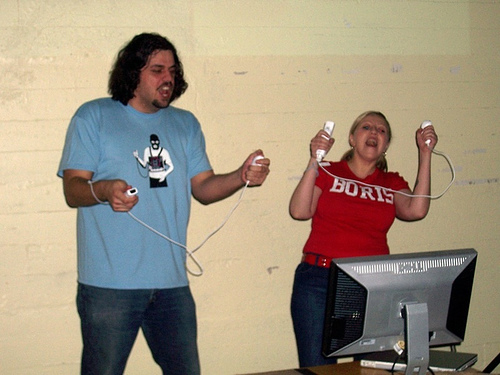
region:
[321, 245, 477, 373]
back of dell monitor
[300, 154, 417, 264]
red shirt reading "boris"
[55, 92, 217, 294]
blue shirt with cartoon print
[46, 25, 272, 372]
man with medium-length black hair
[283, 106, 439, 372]
woman with blonde hair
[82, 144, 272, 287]
white wii controllers in man's hands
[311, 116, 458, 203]
white wii controllers in woman's hands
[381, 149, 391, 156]
hoop earring on woman's left ear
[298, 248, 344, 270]
red belt on woman's waist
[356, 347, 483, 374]
closed laptop on desk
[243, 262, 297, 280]
small gray crack on the wall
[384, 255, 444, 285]
silver words on back of tv set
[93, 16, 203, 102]
bushy black hair on man's head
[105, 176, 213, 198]
white wii remote in man's hand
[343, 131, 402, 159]
huge grin on woman's face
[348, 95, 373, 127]
blond streaks in hair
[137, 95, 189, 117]
small beard on man's face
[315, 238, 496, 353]
back of silver and black television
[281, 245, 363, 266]
shiny red belt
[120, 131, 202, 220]
picture of black and white man on shirt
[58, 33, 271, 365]
man in blue shirt playing wii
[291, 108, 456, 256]
woman in red shirt playing wii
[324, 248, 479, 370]
back of Dell computer monitor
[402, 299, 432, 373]
silver stand holding up computer monitor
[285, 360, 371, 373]
brown wooden table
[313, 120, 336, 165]
white wii controller in a hand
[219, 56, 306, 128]
cream colored brick wall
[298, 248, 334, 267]
red belt in blue jean loop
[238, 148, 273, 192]
white nunchuck in man's hand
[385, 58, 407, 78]
paint chipped off of brick wall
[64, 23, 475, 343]
two people playing wii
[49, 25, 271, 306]
man in a blue shirt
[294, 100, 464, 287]
girl in a red shirt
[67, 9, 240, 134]
man with brown hair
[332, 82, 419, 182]
woman with blonde hair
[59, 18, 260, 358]
man wearing blue jeans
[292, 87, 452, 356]
woman wearing blue jeans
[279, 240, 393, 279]
a red belt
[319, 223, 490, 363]
A Dell computer monitor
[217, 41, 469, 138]
a tan wall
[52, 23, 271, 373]
a man wearing a blue shirt and jeans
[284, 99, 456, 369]
a woman wearing a red shirt and jeans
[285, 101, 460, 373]
a woman holding video game controllers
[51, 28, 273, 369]
a man holding video game controllers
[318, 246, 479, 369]
back of a computer monitor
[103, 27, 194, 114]
man's face with facial hair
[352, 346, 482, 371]
a computer laptop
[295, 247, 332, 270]
a red belt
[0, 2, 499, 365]
a painted tan brick wall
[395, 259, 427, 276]
a corporate logo